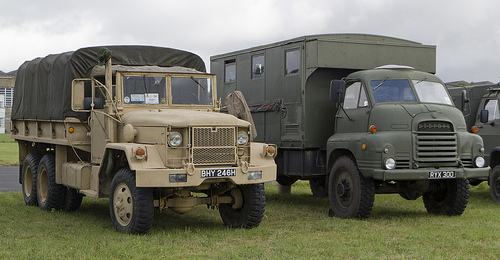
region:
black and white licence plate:
[203, 170, 235, 178]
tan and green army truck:
[18, 58, 272, 211]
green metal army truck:
[211, 32, 482, 223]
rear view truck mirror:
[72, 76, 93, 113]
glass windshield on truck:
[370, 76, 451, 103]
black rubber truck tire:
[328, 157, 374, 214]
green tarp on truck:
[17, 45, 204, 117]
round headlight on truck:
[386, 157, 395, 168]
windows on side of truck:
[220, 48, 301, 78]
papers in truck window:
[124, 93, 159, 104]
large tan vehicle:
[8, 42, 278, 234]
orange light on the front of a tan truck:
[133, 146, 147, 157]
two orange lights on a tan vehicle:
[133, 145, 277, 157]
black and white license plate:
[198, 168, 238, 178]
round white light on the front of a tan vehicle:
[166, 129, 186, 148]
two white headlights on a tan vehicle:
[164, 130, 249, 146]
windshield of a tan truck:
[122, 75, 212, 105]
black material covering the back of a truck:
[8, 43, 207, 123]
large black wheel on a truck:
[323, 158, 375, 220]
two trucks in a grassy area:
[9, 28, 492, 234]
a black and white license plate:
[199, 165, 242, 185]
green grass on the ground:
[276, 218, 318, 248]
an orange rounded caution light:
[62, 120, 89, 140]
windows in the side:
[224, 48, 306, 78]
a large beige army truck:
[16, 51, 283, 227]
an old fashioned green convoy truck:
[284, 28, 466, 187]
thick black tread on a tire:
[134, 194, 151, 229]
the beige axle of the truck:
[157, 193, 244, 208]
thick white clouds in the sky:
[95, 5, 271, 41]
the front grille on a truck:
[403, 120, 465, 168]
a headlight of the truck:
[382, 152, 401, 172]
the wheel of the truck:
[321, 149, 383, 221]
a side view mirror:
[62, 69, 94, 120]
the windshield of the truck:
[116, 70, 221, 110]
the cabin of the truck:
[314, 60, 492, 221]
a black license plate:
[425, 166, 460, 182]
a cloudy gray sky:
[1, 0, 499, 95]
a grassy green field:
[0, 178, 498, 258]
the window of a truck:
[337, 77, 361, 109]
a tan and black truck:
[0, 35, 290, 232]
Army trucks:
[12, 32, 497, 239]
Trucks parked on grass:
[15, 165, 487, 255]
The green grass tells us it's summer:
[5, 195, 485, 256]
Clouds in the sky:
[5, 5, 330, 55]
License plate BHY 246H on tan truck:
[191, 160, 241, 180]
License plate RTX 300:
[425, 160, 461, 180]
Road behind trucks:
[0, 155, 25, 191]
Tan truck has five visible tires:
[20, 146, 270, 231]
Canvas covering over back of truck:
[10, 40, 210, 120]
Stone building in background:
[0, 65, 20, 143]